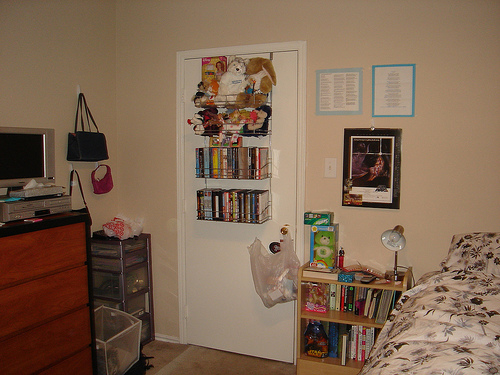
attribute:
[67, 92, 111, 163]
purse — hanging, black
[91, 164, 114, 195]
purse — red, small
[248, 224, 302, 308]
bag — white plastic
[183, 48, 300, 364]
door — white, closed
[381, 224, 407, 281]
lamp — gold, small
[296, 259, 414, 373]
book shelf — wooden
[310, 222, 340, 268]
teddy bear — green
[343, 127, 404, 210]
poster — framed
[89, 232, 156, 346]
storage — plastic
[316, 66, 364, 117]
paper — blue trimmed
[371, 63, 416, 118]
paper — blue trimmed